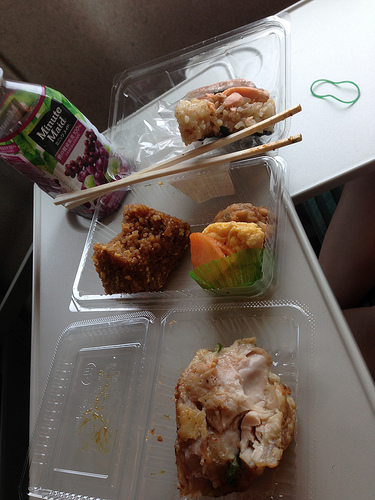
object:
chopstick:
[172, 126, 276, 192]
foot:
[258, 133, 300, 154]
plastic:
[13, 303, 318, 500]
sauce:
[77, 374, 111, 457]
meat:
[33, 357, 154, 468]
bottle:
[0, 70, 132, 222]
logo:
[27, 143, 86, 213]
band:
[310, 78, 360, 103]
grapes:
[64, 174, 110, 238]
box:
[68, 14, 291, 313]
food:
[189, 248, 272, 335]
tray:
[29, 59, 374, 499]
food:
[91, 249, 192, 341]